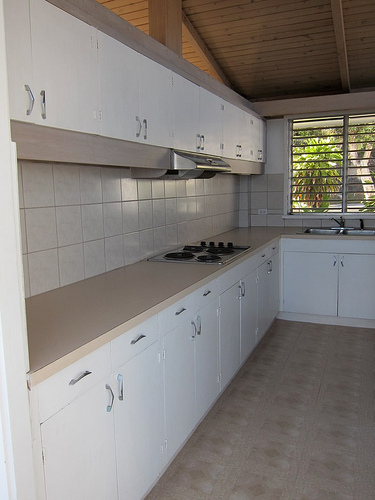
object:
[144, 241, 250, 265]
stove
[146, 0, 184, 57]
beam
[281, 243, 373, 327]
cabinet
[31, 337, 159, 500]
cabinet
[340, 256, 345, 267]
handles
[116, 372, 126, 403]
handles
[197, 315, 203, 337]
handles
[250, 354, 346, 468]
floor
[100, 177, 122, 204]
red barn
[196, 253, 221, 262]
burners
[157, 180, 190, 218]
tile wall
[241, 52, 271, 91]
ground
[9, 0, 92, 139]
cabinet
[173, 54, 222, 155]
cabinet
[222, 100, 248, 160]
cabinet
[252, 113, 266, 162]
cabinet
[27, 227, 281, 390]
beige counter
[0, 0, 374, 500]
kitchen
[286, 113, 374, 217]
blinds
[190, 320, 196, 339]
handles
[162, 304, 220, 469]
cabinet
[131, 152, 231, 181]
hood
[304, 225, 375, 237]
double sink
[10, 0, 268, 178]
row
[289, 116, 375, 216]
window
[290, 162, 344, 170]
slat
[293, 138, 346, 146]
slat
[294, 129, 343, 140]
slat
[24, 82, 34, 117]
handle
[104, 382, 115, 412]
handles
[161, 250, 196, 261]
burner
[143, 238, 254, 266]
cook top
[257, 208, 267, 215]
outlet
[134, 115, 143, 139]
cap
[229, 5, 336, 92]
ceiling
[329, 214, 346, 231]
faucet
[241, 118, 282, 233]
wall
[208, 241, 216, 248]
knobs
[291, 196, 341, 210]
slats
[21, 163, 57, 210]
tile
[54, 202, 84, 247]
tile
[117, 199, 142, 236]
tile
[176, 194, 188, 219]
tile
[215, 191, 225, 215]
tile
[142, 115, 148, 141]
handles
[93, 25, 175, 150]
cabinet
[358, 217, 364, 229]
sprayer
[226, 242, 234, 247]
knobs